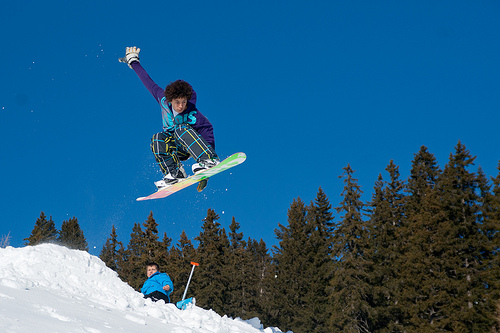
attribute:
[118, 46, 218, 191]
boy — flying, doing a trick, snowboarding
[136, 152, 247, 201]
snowboard — green pink, white, white red, green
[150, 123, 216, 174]
pants — lined blue, yello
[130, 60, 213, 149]
sweatshirt — purple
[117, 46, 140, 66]
glove — white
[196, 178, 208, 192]
glove — white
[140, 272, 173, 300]
jacket — blue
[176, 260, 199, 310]
shovel — blue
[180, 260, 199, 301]
handle — silver, orange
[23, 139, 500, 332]
trees — evergreen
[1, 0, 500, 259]
sky — clear, blue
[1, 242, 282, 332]
ski slope — snow covered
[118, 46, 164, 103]
arm — extended, in the air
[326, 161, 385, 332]
tree — green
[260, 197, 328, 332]
tree — green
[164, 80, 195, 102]
hair — brown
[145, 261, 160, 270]
hair — brown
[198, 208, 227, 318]
tree — green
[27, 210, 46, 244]
tree — green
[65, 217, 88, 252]
tree — green